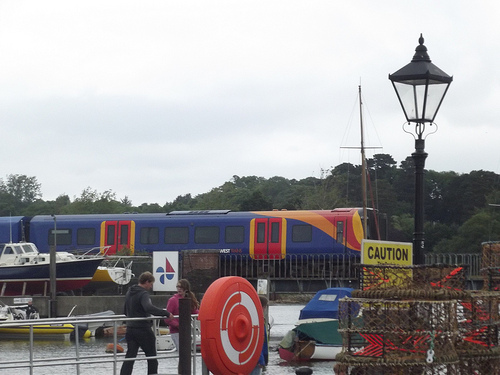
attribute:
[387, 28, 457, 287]
lamp — black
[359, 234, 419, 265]
sign — yellow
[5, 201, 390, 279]
train — blue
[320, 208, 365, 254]
trim — red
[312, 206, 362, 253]
trim — orange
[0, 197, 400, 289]
train — blue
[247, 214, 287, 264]
doors — red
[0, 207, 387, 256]
train — Blue, red and yellow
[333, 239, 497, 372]
containers — Brown , weaved rope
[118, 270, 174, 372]
man — long-sleeve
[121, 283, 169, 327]
hoodie — dark gray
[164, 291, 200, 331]
sweater — pink 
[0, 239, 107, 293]
boat — Red, white and blue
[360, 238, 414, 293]
sign — Yellow 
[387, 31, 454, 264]
street light — black , Tall 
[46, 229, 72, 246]
window — black 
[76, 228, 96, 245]
window — black 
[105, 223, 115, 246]
window — black 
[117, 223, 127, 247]
window — black 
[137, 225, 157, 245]
window — black 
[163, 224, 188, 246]
window — black 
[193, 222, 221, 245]
window — black 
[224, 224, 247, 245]
window — black 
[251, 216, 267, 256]
window — black 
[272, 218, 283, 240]
window — black 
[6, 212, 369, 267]
train car — blue , red , orange 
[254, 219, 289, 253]
train doors — red 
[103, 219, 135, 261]
train doors — red 